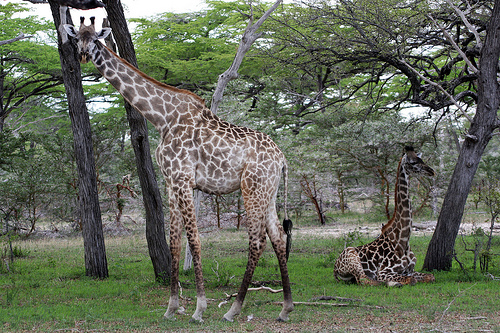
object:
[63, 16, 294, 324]
giraffe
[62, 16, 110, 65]
head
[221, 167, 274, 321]
leg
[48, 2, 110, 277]
tree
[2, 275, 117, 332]
grass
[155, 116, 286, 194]
body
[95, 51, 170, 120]
neck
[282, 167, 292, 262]
tail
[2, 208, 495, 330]
park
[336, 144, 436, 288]
giraffe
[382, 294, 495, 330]
ground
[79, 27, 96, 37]
hair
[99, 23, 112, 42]
ear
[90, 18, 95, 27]
horn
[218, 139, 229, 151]
spots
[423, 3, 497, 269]
trunk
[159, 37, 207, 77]
leaves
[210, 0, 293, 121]
branches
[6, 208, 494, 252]
wild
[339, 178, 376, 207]
distance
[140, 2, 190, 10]
sky